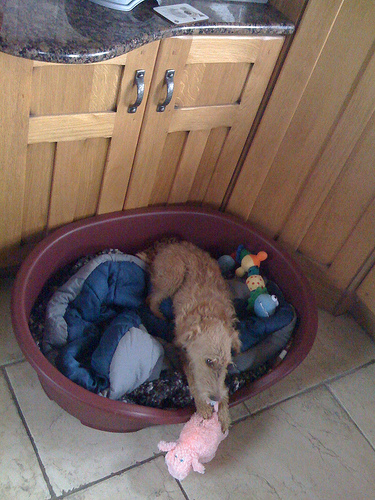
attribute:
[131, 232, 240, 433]
dog — brown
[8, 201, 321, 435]
bin — maroon, plastic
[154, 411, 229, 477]
toy — pink sheep stuffed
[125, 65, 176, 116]
handles — black, metal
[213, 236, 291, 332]
toy — scruffy multicolored caterpillar soft dog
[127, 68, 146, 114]
handle — grey metal cabinet 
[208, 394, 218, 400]
nose — black  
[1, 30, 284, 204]
doors — Wooden cabinet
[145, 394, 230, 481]
pig — pink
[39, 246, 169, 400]
blanket — blue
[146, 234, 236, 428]
dog — brown, fluffy, tan 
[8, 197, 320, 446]
basket — maroon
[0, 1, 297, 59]
countertop — brown, blue, formica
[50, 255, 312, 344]
blanket — blue, grey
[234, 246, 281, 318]
toy — orange, yellow, blue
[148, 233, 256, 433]
dog — scruffy brown terrier mix 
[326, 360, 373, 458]
tile — grey, marble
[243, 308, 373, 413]
tile — grey, marble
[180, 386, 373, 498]
tile — grey, marble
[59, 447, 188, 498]
tile — grey, marble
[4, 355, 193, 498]
tile — grey, marble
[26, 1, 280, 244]
doors — brown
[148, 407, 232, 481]
stuffed toy —  stuffed 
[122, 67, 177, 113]
handles — metal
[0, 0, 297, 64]
counter — marble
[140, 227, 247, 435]
dog — brown, small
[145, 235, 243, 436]
dog — brown, brown terrier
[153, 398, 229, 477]
pink pig — toy, dog toy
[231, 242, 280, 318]
toy — dog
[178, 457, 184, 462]
eye — blue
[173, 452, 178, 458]
eye — blue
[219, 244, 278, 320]
playtoy — stuffed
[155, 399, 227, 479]
toy — pink,  pink sheep stuffed